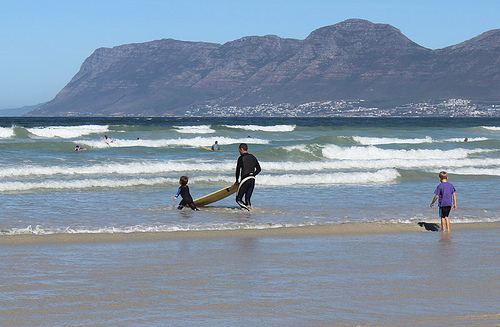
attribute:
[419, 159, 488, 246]
child — young, close, standing, little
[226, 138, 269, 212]
man — enjoying, black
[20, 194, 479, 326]
beach — soaked, brown, wet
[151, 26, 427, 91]
mountains — far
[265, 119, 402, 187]
water — deep, running, rapid, close, crashing, blue, white, background, ripping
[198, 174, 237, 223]
surfboard — white